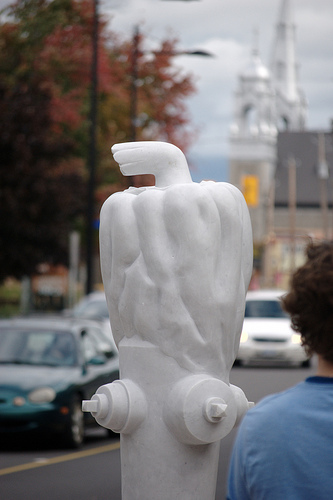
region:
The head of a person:
[273, 230, 328, 377]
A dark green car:
[0, 303, 125, 452]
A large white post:
[69, 135, 255, 498]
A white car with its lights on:
[223, 292, 315, 370]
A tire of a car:
[55, 388, 89, 449]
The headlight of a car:
[26, 382, 59, 407]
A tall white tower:
[233, 19, 278, 254]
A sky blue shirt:
[222, 370, 331, 496]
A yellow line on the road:
[0, 425, 126, 486]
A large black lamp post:
[130, 19, 215, 189]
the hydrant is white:
[79, 133, 250, 488]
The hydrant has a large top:
[82, 127, 270, 360]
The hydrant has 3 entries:
[65, 368, 258, 434]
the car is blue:
[13, 313, 103, 432]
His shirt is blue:
[211, 347, 331, 497]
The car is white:
[238, 283, 296, 363]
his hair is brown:
[269, 234, 330, 338]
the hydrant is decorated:
[97, 137, 253, 332]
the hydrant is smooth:
[93, 202, 242, 465]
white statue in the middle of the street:
[49, 115, 265, 492]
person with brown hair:
[278, 239, 331, 331]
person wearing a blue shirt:
[224, 369, 324, 462]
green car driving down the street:
[2, 315, 101, 439]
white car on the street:
[240, 279, 305, 360]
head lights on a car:
[31, 380, 58, 406]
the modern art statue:
[78, 137, 257, 499]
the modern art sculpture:
[93, 139, 250, 496]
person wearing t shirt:
[223, 221, 330, 497]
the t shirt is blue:
[220, 368, 326, 494]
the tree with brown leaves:
[4, 10, 188, 138]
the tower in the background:
[223, 29, 279, 254]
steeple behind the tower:
[264, 2, 310, 123]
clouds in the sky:
[134, 5, 266, 45]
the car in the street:
[1, 306, 95, 445]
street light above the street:
[124, 32, 212, 73]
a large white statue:
[63, 133, 241, 473]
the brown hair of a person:
[291, 245, 330, 348]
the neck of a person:
[312, 355, 331, 377]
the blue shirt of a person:
[240, 375, 330, 486]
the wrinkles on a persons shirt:
[240, 444, 276, 498]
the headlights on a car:
[27, 379, 61, 418]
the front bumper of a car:
[6, 405, 45, 441]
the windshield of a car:
[1, 322, 74, 372]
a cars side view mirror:
[73, 350, 105, 374]